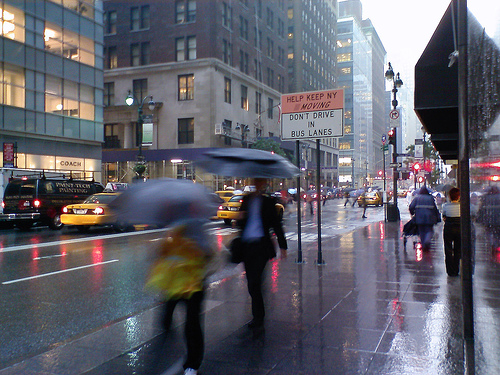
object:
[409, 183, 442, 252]
person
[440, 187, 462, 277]
person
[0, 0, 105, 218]
left buildings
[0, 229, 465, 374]
floor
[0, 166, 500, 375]
road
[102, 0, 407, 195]
building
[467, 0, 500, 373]
glass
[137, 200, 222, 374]
pedestrians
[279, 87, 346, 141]
sign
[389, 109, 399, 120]
sign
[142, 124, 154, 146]
sign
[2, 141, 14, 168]
sign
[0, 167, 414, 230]
traffic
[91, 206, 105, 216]
lights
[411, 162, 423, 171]
light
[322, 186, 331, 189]
umbrella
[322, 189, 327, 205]
person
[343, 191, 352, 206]
person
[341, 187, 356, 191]
umbrella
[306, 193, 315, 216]
person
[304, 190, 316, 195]
umbrella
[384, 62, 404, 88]
street lights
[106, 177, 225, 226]
umbrella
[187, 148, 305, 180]
umbrella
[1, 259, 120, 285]
lines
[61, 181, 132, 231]
car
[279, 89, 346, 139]
signpost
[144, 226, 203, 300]
raincoat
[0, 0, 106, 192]
building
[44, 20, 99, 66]
window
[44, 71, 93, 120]
window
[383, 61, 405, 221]
light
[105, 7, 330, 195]
wall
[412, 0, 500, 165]
street sign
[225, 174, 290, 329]
people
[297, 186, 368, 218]
pederstrians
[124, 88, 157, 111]
street light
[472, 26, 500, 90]
water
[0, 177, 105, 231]
van